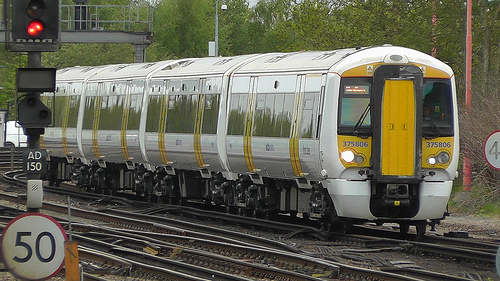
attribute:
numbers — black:
[12, 229, 59, 264]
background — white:
[2, 218, 62, 276]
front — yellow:
[336, 59, 454, 176]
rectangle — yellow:
[380, 73, 421, 178]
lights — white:
[339, 149, 444, 167]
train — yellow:
[229, 0, 461, 240]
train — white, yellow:
[39, 48, 460, 234]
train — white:
[31, 38, 462, 242]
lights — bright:
[338, 145, 457, 167]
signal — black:
[5, 1, 62, 53]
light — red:
[2, 9, 77, 59]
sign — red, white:
[0, 211, 78, 279]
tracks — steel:
[83, 152, 288, 279]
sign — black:
[23, 147, 46, 176]